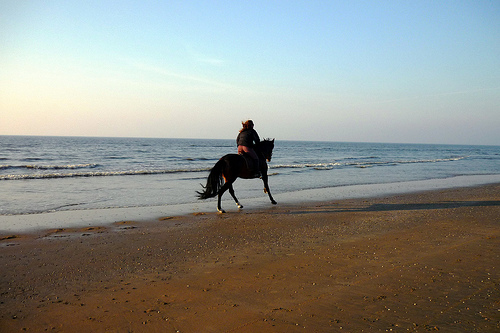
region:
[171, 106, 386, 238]
a woman riding a horse on the beach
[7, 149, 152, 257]
low ocean waves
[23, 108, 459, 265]
beach scene at sun set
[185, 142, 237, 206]
tail of a horse blowing in the wind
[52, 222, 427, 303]
pebbles on a beach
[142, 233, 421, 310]
wet sand on a beach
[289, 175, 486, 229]
shadow of a woman riding a horse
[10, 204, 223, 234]
foot prints left by a horse in sand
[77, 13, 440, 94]
clear blue sky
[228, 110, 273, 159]
back of a woman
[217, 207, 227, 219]
The hoof of the horse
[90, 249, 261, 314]
The sand looks rocky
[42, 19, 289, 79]
A clear sky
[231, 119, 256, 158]
A woman riding her horse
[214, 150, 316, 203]
A horse galloping on the sand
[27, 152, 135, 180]
Waves crashing on the on shore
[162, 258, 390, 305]
the sand is brown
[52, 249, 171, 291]
rocks on the sand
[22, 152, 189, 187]
very small waves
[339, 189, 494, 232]
A shadow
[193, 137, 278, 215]
A horse on a beach.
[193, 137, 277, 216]
A horse running on a beach.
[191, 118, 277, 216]
A girl riding a horse.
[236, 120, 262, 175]
A girl in red pants.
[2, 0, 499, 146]
A bright blue sky.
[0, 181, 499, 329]
Sand on a beach.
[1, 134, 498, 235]
A blue ocean at sunset.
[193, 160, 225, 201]
A horses black tail.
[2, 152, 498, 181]
Small waves in the sea.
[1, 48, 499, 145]
A lightly cloudy sky.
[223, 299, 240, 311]
a footstep in the sand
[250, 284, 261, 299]
a footstep in the sand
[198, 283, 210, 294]
a footstep in the sand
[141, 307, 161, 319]
a footstep in the sand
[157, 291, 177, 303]
a footstep in the sand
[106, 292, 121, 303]
a footstep in the sand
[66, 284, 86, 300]
a footstep in the sand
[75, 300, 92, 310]
a footstep in the sand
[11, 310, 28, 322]
a footstep in the sand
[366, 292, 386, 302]
a footstep in the sand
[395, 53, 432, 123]
The color of the sky is a very, very light blue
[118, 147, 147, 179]
The color of the water is an off brown color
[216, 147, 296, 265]
This horse is a deep brown color and strong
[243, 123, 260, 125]
This rider has dark brown hair in color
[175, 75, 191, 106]
There are many, many clouds in the sky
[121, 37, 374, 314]
The photo taken was taken by James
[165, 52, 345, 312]
Mick Jones is the owner of the brown horse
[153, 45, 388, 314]
This photo was taken with a wide-angle lens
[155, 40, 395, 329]
This photo was taken by a large photography firm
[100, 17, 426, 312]
Nancy is the name of the person on the horse